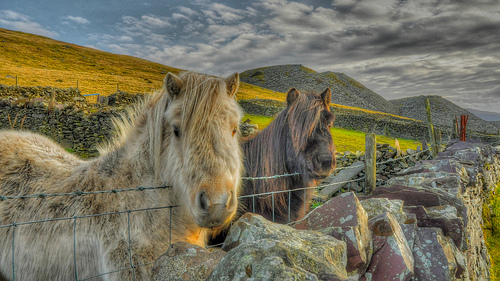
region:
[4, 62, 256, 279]
a horse with long brown hair.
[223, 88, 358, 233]
a horse with long dark brown hair.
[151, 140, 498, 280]
a stone wall near horses.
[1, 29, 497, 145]
a grass and flower covered hillside.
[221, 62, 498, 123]
a grass covered hillside.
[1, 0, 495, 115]
a cloudy blue sky.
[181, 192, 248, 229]
a nose on a horse.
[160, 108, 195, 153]
a horse right eye.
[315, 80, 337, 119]
a horse left ear.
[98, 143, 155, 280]
a horse neck.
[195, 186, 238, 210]
The nose of the white horse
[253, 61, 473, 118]
Hills behind the horse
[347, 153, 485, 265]
A stone wall by the horses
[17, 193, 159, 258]
A wire fence in front of the horses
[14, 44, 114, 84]
A grassy hill behind the horses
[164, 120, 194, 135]
The right eye of the horse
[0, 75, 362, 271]
Two horses by a fence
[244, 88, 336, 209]
A gray horse by a fence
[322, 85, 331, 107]
The left ear of the gray horse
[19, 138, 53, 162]
The white fur of the horse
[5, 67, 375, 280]
two horses standing in the pasture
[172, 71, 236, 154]
white hair swooping over the face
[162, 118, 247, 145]
two black eyes on either side of the head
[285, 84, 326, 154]
hair covering the eye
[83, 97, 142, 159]
white hair sticking off the neck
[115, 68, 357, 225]
heads leaning over the fence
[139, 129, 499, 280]
rock formation along the fence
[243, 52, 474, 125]
three hills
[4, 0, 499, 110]
sky covered in gray clouds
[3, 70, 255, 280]
hairy white horse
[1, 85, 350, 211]
these are two horses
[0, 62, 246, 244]
the horse is fury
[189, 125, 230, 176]
the horse is brown in color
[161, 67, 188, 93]
this is the ear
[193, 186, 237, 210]
the nose is in front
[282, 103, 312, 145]
the eye is closed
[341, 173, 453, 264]
the rocks are big in size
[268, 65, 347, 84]
this is a hill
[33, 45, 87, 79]
the grass are brown in color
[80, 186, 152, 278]
this is a grilled fence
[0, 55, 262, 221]
the horse is looking at the camera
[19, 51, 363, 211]
there are 2 horses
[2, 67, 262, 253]
the horse is beige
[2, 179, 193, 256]
the fence is grey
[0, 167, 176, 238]
the fence is metal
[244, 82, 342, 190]
the horse is brown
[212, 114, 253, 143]
the eye is brown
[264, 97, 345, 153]
hair is covering one eye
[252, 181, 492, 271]
rocks in front of horses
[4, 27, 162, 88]
the hill is golden brown